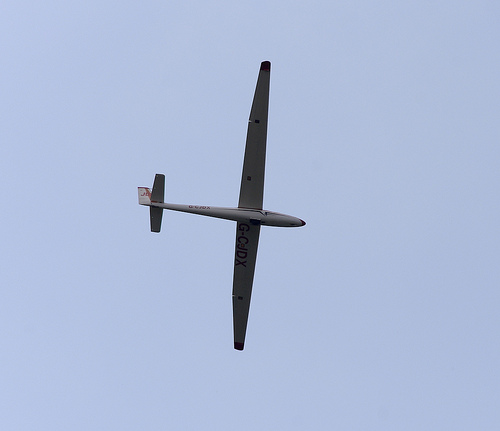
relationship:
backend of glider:
[104, 137, 184, 262] [137, 60, 306, 351]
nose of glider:
[290, 214, 307, 231] [137, 60, 306, 351]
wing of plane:
[236, 56, 275, 210] [67, 56, 341, 366]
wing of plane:
[236, 56, 275, 210] [107, 52, 318, 382]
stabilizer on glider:
[136, 184, 150, 207] [137, 60, 306, 351]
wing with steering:
[236, 56, 275, 210] [246, 116, 259, 125]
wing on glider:
[230, 224, 264, 349] [137, 60, 306, 351]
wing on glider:
[236, 56, 275, 210] [137, 60, 306, 351]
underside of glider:
[143, 197, 305, 233] [137, 60, 306, 351]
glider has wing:
[137, 60, 306, 351] [239, 60, 272, 209]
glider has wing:
[137, 60, 306, 351] [229, 222, 258, 349]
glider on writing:
[137, 60, 306, 351] [177, 201, 200, 213]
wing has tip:
[230, 224, 264, 350] [230, 340, 245, 351]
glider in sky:
[126, 52, 318, 369] [331, 49, 498, 404]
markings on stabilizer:
[138, 185, 151, 198] [136, 184, 150, 207]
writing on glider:
[173, 203, 214, 215] [136, 60, 306, 351]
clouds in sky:
[278, 86, 459, 224] [1, 3, 499, 428]